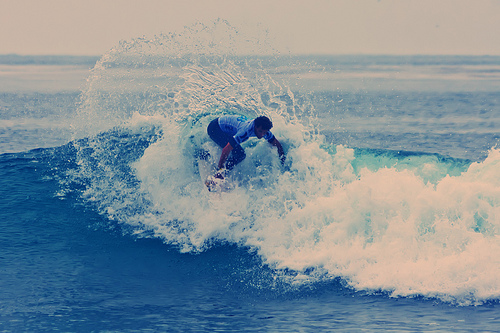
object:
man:
[203, 114, 287, 190]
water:
[16, 63, 103, 159]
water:
[113, 291, 146, 307]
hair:
[252, 115, 272, 129]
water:
[17, 237, 85, 301]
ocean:
[0, 53, 499, 113]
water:
[234, 278, 323, 326]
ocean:
[273, 236, 490, 331]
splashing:
[77, 18, 293, 114]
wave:
[293, 139, 351, 194]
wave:
[63, 120, 172, 188]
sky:
[324, 17, 454, 45]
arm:
[263, 131, 285, 156]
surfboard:
[197, 159, 229, 193]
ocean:
[55, 251, 254, 321]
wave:
[185, 69, 283, 113]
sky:
[0, 0, 227, 59]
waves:
[258, 126, 495, 309]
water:
[146, 183, 238, 304]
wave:
[94, 43, 222, 110]